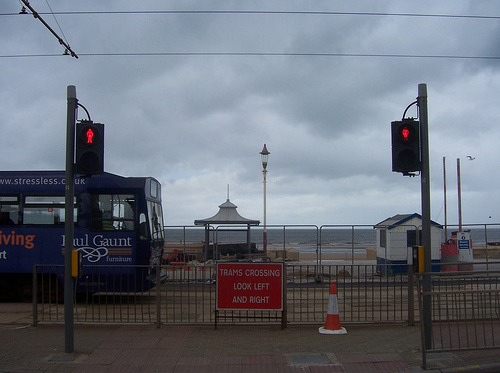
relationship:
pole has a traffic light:
[414, 81, 440, 357] [389, 108, 424, 179]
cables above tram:
[65, 1, 499, 66] [14, 172, 163, 290]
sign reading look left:
[218, 260, 280, 315] [223, 280, 274, 293]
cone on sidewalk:
[328, 281, 338, 293] [107, 336, 275, 372]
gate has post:
[84, 268, 420, 302] [153, 264, 167, 274]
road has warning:
[168, 283, 205, 327] [459, 236, 469, 252]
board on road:
[459, 247, 474, 263] [168, 283, 205, 327]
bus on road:
[83, 181, 159, 285] [168, 283, 205, 327]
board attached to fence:
[459, 247, 474, 263] [293, 266, 409, 300]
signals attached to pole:
[72, 111, 108, 180] [414, 81, 440, 357]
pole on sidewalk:
[414, 81, 440, 357] [107, 336, 275, 372]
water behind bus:
[290, 240, 312, 253] [83, 181, 159, 285]